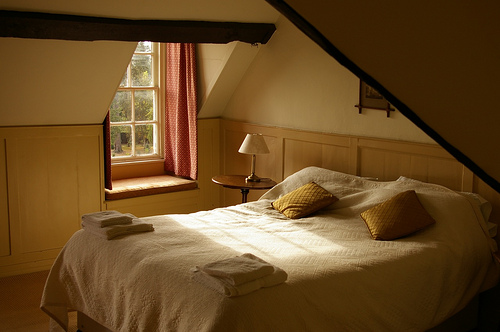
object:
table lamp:
[238, 133, 270, 182]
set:
[188, 252, 287, 297]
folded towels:
[201, 252, 275, 287]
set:
[78, 208, 154, 242]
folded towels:
[81, 210, 133, 228]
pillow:
[359, 189, 436, 241]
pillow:
[271, 181, 340, 219]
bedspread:
[40, 166, 493, 332]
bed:
[72, 166, 495, 332]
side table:
[211, 174, 277, 204]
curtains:
[163, 43, 198, 180]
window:
[109, 41, 167, 161]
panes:
[128, 86, 159, 125]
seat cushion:
[104, 174, 197, 201]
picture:
[354, 78, 396, 118]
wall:
[220, 47, 316, 106]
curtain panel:
[103, 109, 112, 190]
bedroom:
[1, 0, 500, 332]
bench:
[103, 174, 198, 202]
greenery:
[133, 56, 154, 80]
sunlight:
[165, 201, 346, 262]